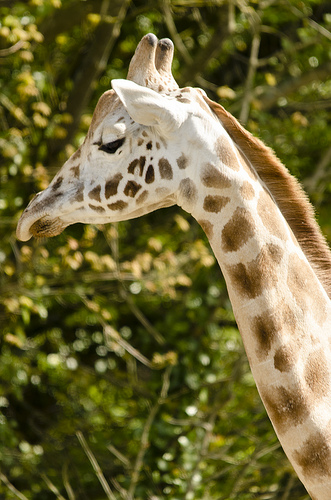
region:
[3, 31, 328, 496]
giraffe standing in front of tree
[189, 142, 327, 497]
brown spots on giraffe's neck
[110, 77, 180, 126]
white ear of girafee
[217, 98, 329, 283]
brown mane on giraffe's neck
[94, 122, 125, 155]
eye of the giraffe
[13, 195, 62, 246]
mouth of the giraffe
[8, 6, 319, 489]
trees behind the giraffe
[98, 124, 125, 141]
white eyelid of the giraffe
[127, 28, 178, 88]
short horns of the giraffe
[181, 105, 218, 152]
white spot on giraffe's head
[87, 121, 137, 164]
Eyes of a giraffe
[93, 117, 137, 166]
Eye of a giraffe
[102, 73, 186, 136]
Ear of a giraffe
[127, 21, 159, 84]
Horn of a giraffe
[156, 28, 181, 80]
Horn of a giraffe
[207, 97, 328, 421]
Neck of a giraffe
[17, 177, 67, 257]
Mouth of a giraffe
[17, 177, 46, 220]
Nose of a giraffe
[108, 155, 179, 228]
Dots of a giraffe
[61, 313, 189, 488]
This is a tree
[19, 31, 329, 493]
giraffe standing in front of green trees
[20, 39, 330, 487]
head and neck of giraffe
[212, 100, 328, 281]
short hair of mane on giraffe's neck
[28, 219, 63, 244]
bottom lip of giraffe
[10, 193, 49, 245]
top lip of giraffe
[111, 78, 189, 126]
white ear of giraffe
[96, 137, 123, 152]
black eyelashes of giraffe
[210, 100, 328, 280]
brown hair of giraffe's mane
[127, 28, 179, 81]
two tiny horns on giraffe's head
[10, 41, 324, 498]
this is a giraffe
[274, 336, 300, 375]
a brown spot on the giraffe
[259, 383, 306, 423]
a brown spot on the giraffe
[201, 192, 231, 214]
a brown spot on the giraffe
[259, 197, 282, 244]
a brown spot on the giraffe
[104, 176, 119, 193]
a brown spot on the giraffe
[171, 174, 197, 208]
a brown spot on the giraffe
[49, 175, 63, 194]
a brown spot on the giraffe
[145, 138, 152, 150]
a brown spot on the giraffe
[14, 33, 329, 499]
The head and neck of a giraffe.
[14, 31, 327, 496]
The head neck of a giraffe.